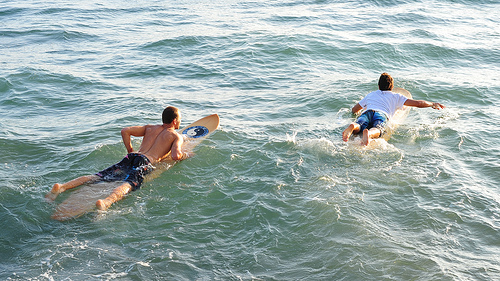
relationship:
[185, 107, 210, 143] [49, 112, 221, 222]
logo visible on surfboard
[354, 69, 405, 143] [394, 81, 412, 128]
man on a surfboard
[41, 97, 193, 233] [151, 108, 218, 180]
man on a surfboard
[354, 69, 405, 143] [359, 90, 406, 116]
man wearing white shirt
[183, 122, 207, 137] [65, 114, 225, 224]
logo on surfboard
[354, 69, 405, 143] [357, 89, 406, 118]
man wears t-shirt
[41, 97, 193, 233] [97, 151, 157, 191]
man wearing swim trunks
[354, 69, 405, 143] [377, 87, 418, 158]
man riding surfboard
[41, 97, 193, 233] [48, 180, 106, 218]
man has feet